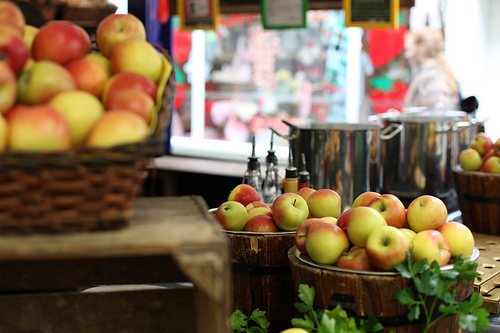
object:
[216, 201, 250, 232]
apple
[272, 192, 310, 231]
apples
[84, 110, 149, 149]
apples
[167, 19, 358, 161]
window light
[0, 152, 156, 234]
basket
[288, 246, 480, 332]
basket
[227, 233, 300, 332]
basket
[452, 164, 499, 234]
basket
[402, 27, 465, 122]
person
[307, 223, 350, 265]
apple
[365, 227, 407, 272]
apple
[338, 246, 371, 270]
apple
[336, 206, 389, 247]
apple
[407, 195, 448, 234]
apple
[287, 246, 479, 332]
barrel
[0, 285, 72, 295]
space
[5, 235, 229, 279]
wood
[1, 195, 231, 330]
bench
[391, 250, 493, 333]
plants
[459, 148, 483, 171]
apples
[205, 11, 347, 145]
window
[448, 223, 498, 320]
table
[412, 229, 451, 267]
apple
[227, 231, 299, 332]
barrels